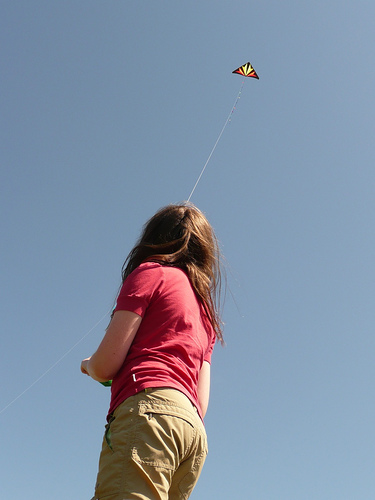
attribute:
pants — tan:
[92, 385, 209, 498]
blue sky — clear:
[57, 64, 141, 175]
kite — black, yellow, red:
[229, 62, 256, 80]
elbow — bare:
[87, 343, 135, 407]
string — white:
[182, 80, 240, 210]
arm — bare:
[93, 334, 121, 373]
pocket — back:
[130, 401, 195, 470]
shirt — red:
[98, 256, 222, 425]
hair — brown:
[102, 197, 245, 350]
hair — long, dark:
[104, 223, 267, 294]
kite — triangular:
[232, 60, 259, 79]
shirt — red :
[106, 261, 214, 422]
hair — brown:
[121, 204, 226, 349]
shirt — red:
[88, 259, 238, 409]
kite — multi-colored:
[232, 61, 259, 80]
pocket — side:
[104, 409, 121, 464]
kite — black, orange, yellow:
[229, 58, 261, 82]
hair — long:
[170, 221, 219, 268]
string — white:
[153, 71, 362, 302]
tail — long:
[222, 76, 263, 139]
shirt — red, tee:
[93, 244, 243, 428]